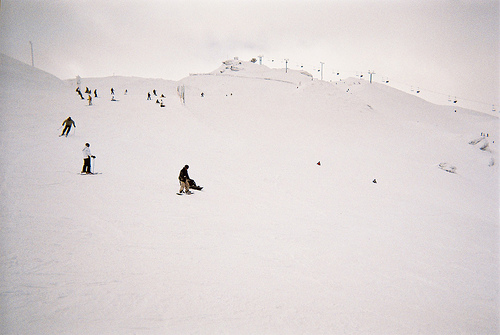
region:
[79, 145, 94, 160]
person wearing a white coat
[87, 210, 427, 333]
the snow is white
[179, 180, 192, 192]
person wearing brown pants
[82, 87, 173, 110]
people skiing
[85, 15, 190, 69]
clouds in the sky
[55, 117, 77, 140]
a person skiing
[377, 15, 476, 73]
the sky is cloudy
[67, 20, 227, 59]
clouds are in the sky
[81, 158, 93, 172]
person wearing black pants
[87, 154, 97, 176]
person holding ski pole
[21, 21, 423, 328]
Picture taken outdoors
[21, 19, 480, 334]
picture taken during the day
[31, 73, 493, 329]
snow on a mountain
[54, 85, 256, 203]
people are skiing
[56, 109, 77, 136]
a man is holding ski poles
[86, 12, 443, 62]
the sky is full of clouds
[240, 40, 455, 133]
a sky lift is seen in the background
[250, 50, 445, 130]
The ski lift has chairs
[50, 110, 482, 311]
It is winter time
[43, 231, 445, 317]
The bottom has now skiers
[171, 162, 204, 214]
skier on the mountain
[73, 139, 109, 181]
skier on the mountain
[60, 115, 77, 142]
skier on the mountain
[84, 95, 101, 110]
skier on the mountain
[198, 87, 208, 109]
skier on the mountain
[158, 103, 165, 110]
skier on the mountain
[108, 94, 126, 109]
skier on the mountain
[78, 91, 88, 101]
skier on the mountain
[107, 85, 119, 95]
skier on the mountain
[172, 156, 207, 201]
a man skiing down a mountain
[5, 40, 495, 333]
hill of fresh white snow on the ground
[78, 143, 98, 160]
white winter jacket for skiing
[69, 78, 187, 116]
a group of skiers coming down the mountain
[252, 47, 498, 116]
chairlift bringing skiers up the mountain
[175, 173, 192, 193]
brown ski pants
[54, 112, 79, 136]
person using ski poles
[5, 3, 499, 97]
gray and white sky above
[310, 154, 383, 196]
two people coming down the hill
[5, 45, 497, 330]
bright white powdered snow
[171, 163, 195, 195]
a person standing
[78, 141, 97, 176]
a person standing in the snow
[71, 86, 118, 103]
people skiing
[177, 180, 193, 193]
person wearing tanned pants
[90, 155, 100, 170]
person holding ski poles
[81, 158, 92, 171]
person wearing pants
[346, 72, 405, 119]
a mountain of snow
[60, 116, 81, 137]
a person skiing downhill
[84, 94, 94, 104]
person standing in the snow